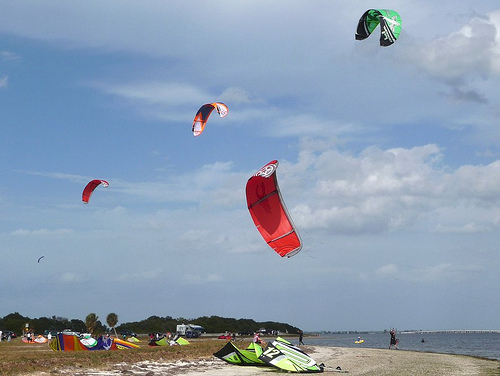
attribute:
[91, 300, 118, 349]
leaves — green